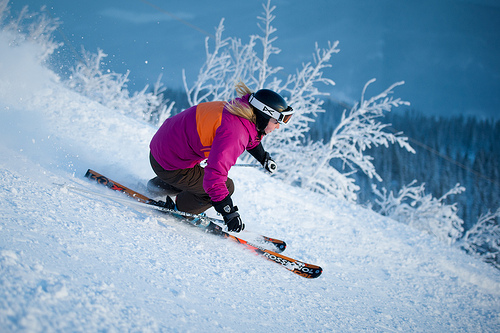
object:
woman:
[146, 79, 295, 234]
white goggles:
[247, 90, 295, 126]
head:
[245, 88, 286, 136]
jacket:
[148, 92, 264, 203]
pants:
[148, 150, 235, 214]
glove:
[210, 193, 247, 235]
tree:
[175, 1, 415, 209]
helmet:
[251, 87, 290, 113]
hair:
[219, 81, 256, 120]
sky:
[0, 2, 499, 123]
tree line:
[312, 92, 500, 129]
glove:
[245, 142, 279, 176]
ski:
[82, 161, 325, 280]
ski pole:
[48, 180, 226, 226]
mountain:
[0, 30, 499, 332]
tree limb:
[294, 75, 418, 208]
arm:
[201, 119, 249, 212]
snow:
[0, 0, 499, 331]